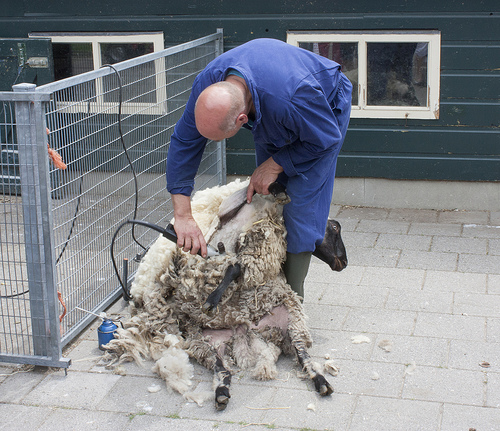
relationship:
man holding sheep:
[158, 35, 364, 347] [127, 195, 362, 407]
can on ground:
[95, 313, 121, 353] [2, 166, 498, 429]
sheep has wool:
[105, 174, 343, 406] [152, 344, 207, 409]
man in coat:
[165, 29, 360, 324] [160, 32, 350, 259]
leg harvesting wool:
[288, 312, 322, 397] [105, 174, 337, 397]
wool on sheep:
[165, 263, 207, 297] [182, 207, 301, 381]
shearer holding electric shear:
[178, 49, 401, 317] [152, 217, 223, 264]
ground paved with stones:
[359, 223, 473, 428] [383, 244, 475, 390]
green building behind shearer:
[468, 77, 476, 98] [137, 214, 200, 274]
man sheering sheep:
[169, 29, 360, 175] [126, 148, 368, 396]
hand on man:
[133, 107, 245, 232] [171, 4, 382, 346]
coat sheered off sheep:
[106, 169, 330, 405] [124, 172, 351, 415]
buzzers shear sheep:
[163, 217, 235, 270] [103, 198, 350, 404]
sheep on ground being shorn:
[105, 174, 343, 406] [162, 205, 308, 360]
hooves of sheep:
[132, 330, 397, 415] [192, 188, 274, 321]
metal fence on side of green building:
[0, 62, 171, 365] [341, 0, 496, 178]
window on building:
[285, 32, 440, 109] [3, 0, 499, 194]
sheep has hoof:
[105, 174, 343, 406] [213, 384, 231, 409]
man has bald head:
[169, 29, 360, 175] [192, 81, 247, 143]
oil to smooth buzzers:
[72, 304, 118, 350] [109, 216, 221, 298]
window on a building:
[285, 32, 440, 109] [362, 1, 483, 179]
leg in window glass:
[288, 312, 322, 397] [367, 41, 428, 105]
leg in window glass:
[288, 312, 322, 397] [300, 40, 360, 108]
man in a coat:
[169, 29, 360, 175] [168, 42, 353, 251]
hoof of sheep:
[313, 377, 331, 393] [133, 174, 350, 391]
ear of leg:
[232, 112, 250, 131] [288, 312, 322, 397]